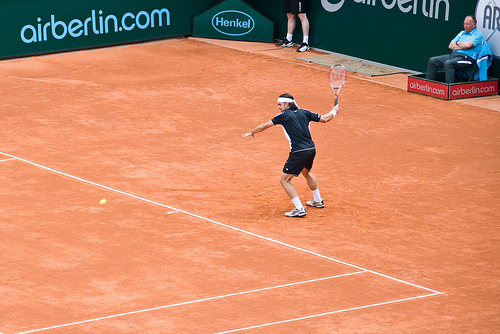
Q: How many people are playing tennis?
A: One.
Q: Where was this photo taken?
A: At the tennis court.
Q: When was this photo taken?
A: During the day.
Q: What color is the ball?
A: Yellow.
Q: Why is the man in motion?
A: He is hitting the ball.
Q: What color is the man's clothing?
A: Dark blue.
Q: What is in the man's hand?
A: A tennis racket.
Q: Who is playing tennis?
A: The man.